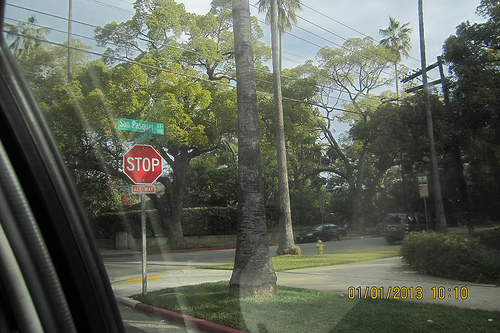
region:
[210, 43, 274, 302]
Large brown tree trunk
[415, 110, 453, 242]
Large brown tree trunk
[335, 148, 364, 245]
Large brown tree trunk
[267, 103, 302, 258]
Large brown tree trunk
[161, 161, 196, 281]
Large brown tree trunk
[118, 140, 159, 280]
Red and white traffic sign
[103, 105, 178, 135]
Green and white street sign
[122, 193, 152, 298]
Large metal post in the ground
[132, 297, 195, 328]
Red edge to pavement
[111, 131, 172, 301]
stop sign at the end of the sidewalk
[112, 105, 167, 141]
a street sign is above the stop sign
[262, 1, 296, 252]
a palm tree is in the distance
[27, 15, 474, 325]
the window for the vehicle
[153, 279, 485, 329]
grass grows in the medium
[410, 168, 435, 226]
a road sign is off to the right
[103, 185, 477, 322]
the road the vehicles drive on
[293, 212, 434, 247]
two vehicles are on the road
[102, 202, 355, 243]
the line of hedges are across the street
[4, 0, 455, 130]
power lines run above the road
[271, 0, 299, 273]
Trunk of a tree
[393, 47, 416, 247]
Trunk of a tree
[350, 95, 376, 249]
Trunk of a tree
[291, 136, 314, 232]
Trunk of a tree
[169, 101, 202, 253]
Trunk of a tree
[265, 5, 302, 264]
Trunk of a tree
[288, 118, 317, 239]
Trunk of a tree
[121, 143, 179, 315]
Stop sign on a street corner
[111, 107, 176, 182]
Street sign with street names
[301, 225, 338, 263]
Fire hydrant on side of road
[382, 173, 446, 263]
SUV parked on street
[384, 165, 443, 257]
SUV parked by sign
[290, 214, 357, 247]
Car parked on street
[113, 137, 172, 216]
All way stop sign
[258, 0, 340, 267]
Fire hydrant by palm tree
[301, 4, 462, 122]
Power lines above street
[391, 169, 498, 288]
Sign next to bushes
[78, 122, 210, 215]
a red signal on board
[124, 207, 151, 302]
a iron rod in road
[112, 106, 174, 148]
a green board in top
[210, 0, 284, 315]
a long tree in ground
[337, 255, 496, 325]
a timer display in pic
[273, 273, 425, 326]
green grass on ground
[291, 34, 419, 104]
electric lines in the top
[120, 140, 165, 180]
a red and white stop sign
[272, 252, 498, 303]
a small sidewalk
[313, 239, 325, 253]
a yellow fire hydrant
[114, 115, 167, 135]
a green and white sign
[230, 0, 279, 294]
a tall tree trunk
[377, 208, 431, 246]
the back of an suv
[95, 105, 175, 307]
stop sign with street sign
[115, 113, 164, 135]
street sign on corner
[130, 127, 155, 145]
street sign on corner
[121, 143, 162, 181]
Stop sign on corner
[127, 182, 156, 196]
sign stating ALL WAY below STOP sign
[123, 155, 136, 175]
Letter S of stop sign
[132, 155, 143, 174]
Letter T of stop sign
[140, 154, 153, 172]
Letter O of stop sign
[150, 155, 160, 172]
Letter P of stop sign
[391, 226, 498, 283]
bush on corner around sidewalk